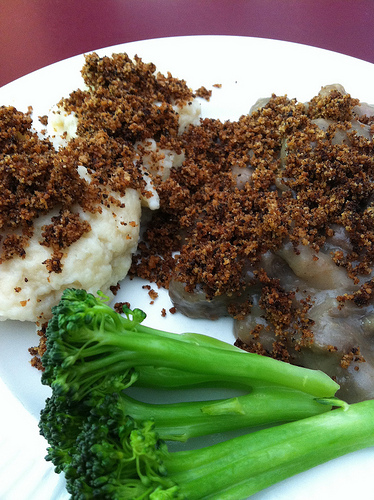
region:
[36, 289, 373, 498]
a green vegetable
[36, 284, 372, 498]
broccoli up front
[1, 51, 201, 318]
white mashed potatoes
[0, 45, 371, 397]
breadcrumbs sprinkled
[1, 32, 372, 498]
a white plate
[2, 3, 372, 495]
table holding everything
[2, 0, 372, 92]
a purple table standing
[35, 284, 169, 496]
the sprouts are full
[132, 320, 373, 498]
the stem is tough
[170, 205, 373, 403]
gravy on side of plate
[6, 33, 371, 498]
a white plate is under the food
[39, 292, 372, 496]
green broccoli is on the plate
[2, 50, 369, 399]
a spread made of brown seeds is on the dish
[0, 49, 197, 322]
the seeds are sprinkled over the mashed potatoes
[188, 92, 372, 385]
a gravy is under the granola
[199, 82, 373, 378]
white chunks are in the gravy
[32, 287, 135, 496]
the heads of the broccoli have buds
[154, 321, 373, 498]
broccoli has stems lying on the plate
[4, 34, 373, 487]
the white plate is ceramic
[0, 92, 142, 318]
a portion of polenta is on the dish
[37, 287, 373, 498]
the brocolli is green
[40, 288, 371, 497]
the broccoli is on the plate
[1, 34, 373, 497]
white plate is circular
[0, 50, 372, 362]
crumbled bacon on top is brown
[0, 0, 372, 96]
table under plate is purple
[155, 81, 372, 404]
cream sauce on meat under bacon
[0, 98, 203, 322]
white mashed potatoes on plate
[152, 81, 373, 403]
creamsauce under bacon is grey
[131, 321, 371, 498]
large stalks on broccoli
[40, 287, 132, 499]
dark green tips on broccoli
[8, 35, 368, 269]
FOOD IS BEING SERVED ON PLATE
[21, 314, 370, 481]
GREEN VEGETABLE IS BROCCOLI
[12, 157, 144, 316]
SERVING OF MASHED POTATOES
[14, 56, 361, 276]
BACON BITS SPRINKLED OVER FOOD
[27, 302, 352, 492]
BROCCOLI IS SERVED IN SPEARS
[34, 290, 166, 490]
FLORETS ON BROCCOLI SPEARS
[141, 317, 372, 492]
STALKS ON BROCCOLI SPEARS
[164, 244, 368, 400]
GRAVY TYPE FOOD ON PLATE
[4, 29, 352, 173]
PLATE IS ROUND IN SHAPE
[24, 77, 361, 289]
BACON BITS ARE BROWN IN COLOR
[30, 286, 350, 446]
piece of brocolli on a plate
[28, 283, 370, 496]
three pieces of brocolli on a plate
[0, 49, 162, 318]
mashed potatoes with seasoning on top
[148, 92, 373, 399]
grave with seasoning on top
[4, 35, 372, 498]
white plate with vegetable items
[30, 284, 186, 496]
top of the broccoli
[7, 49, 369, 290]
heavy brown seasoning on mashed potatoes and gravy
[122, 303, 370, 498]
stem of the broccoli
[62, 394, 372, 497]
a piece of steamed broccoli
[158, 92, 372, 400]
gravy on a plate